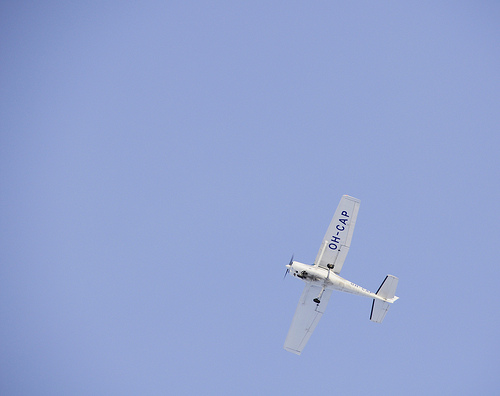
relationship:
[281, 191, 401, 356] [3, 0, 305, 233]
plane flying across sky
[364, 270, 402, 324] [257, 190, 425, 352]
tail on plane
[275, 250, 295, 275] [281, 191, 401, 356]
propellers on plane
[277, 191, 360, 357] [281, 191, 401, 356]
wings on plane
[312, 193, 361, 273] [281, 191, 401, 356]
wing on plane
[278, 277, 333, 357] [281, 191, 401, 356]
wing on plane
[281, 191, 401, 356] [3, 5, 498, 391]
plane flying in air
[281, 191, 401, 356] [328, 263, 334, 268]
plane has wheel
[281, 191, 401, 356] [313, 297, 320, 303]
plane has wheel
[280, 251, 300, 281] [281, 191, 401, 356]
propeller of plane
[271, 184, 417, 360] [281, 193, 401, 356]
bottom of plane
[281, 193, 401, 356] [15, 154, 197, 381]
plane in sky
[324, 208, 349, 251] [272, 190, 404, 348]
number of plane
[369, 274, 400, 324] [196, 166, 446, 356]
tail on plane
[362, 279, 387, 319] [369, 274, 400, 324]
stripe on tail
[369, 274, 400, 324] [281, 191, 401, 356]
tail of plane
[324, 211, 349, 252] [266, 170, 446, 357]
writing on plane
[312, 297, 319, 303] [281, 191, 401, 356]
wheel on plane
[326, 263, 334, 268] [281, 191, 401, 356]
wheel on plane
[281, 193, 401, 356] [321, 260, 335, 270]
plane has wheels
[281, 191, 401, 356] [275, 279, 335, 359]
plane has wing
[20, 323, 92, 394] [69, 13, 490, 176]
clouds in sky